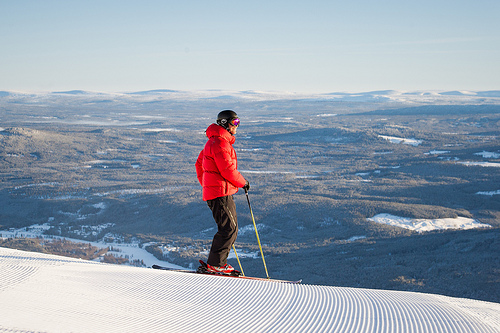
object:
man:
[195, 108, 251, 273]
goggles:
[227, 117, 241, 128]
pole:
[243, 190, 273, 280]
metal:
[243, 188, 271, 278]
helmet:
[217, 110, 238, 129]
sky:
[0, 11, 500, 86]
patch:
[367, 211, 494, 233]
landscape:
[2, 87, 497, 304]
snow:
[377, 134, 424, 146]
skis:
[152, 264, 303, 284]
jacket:
[194, 123, 246, 201]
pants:
[207, 195, 239, 266]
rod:
[231, 243, 248, 278]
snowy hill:
[368, 212, 493, 233]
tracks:
[146, 260, 308, 285]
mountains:
[0, 86, 500, 109]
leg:
[207, 202, 239, 264]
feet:
[208, 262, 235, 272]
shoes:
[206, 263, 235, 273]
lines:
[172, 284, 499, 332]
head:
[216, 110, 240, 135]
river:
[2, 214, 137, 247]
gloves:
[242, 178, 250, 191]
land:
[325, 193, 493, 261]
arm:
[215, 139, 242, 186]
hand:
[242, 178, 250, 193]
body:
[200, 134, 237, 195]